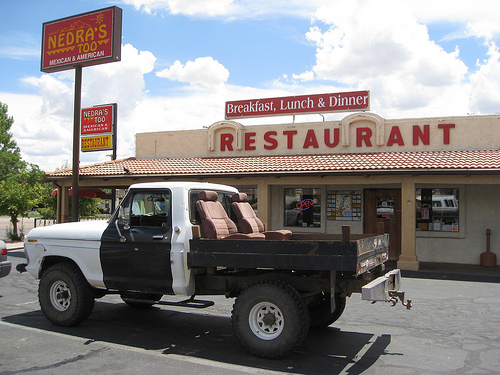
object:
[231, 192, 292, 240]
car seats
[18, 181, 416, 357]
truck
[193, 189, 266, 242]
car seat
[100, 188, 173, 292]
door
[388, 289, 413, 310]
trailer hitch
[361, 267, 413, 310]
bumper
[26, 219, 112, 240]
hood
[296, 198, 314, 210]
open sign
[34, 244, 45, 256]
gas cap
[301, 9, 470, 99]
clouds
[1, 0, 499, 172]
sky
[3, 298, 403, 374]
shadow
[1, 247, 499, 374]
parking lot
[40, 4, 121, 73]
restaurant sign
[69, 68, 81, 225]
pole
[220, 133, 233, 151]
letters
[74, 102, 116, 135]
restaurant sign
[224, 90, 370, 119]
restaurant sign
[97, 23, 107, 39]
yellow writing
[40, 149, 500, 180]
roof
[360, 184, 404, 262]
door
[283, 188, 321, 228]
window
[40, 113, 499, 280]
restaurant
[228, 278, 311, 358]
back tire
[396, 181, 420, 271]
pillar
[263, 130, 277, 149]
letter s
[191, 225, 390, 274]
bed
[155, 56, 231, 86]
cloud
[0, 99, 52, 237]
tree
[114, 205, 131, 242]
side mirror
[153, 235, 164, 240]
door handle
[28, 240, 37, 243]
front left flasher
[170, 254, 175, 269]
dent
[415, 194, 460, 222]
car reflection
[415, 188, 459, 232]
window